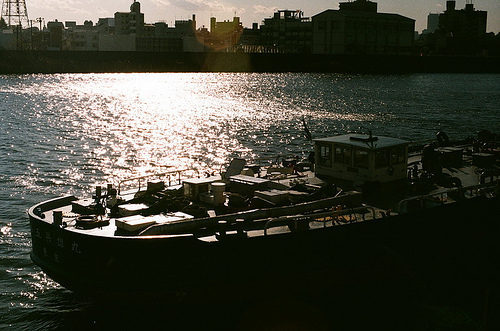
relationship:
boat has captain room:
[29, 97, 499, 312] [318, 130, 405, 185]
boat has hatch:
[29, 97, 497, 312] [109, 215, 162, 234]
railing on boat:
[264, 204, 376, 227] [20, 119, 499, 325]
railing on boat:
[395, 182, 498, 209] [20, 119, 499, 325]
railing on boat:
[119, 166, 202, 197] [20, 119, 499, 325]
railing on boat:
[218, 152, 297, 168] [20, 119, 499, 325]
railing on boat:
[409, 138, 432, 149] [20, 119, 499, 325]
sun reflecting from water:
[75, 83, 257, 138] [6, 76, 485, 135]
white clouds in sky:
[3, 1, 498, 37] [41, 1, 326, 9]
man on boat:
[420, 141, 445, 185] [20, 119, 499, 325]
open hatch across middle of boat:
[222, 158, 244, 182] [29, 97, 499, 312]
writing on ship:
[3, 200, 110, 292] [29, 130, 496, 308]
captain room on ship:
[318, 130, 405, 185] [29, 130, 496, 308]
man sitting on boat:
[420, 141, 445, 185] [29, 97, 499, 312]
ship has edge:
[27, 132, 498, 290] [137, 234, 173, 240]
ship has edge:
[24, 111, 496, 328] [183, 225, 340, 270]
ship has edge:
[29, 130, 496, 308] [193, 182, 387, 243]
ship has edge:
[29, 130, 496, 308] [153, 184, 491, 246]